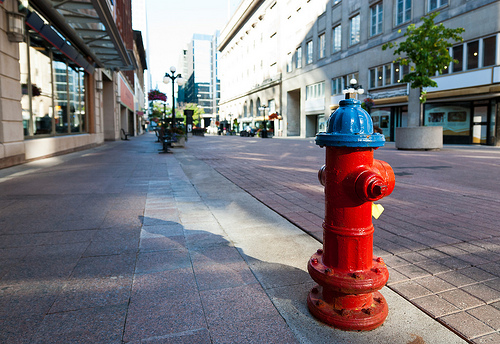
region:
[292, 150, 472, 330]
the hydrant is red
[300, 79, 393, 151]
the top is blue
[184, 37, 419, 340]
the hydrant is at the sidewalk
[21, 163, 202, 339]
the floor is bricked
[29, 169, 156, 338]
the ground is red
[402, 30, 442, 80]
the leaves are green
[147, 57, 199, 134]
the lamp post is off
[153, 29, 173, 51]
the sky is white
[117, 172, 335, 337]
the shadow on the ground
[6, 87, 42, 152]
the wall is beige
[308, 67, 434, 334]
Fire hydrant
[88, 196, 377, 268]
Brick pavers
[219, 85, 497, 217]
Stores along the walkway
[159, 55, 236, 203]
Street lights along the walkway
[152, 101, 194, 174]
Benches along the walkway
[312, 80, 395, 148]
Blue top on the fire hydrant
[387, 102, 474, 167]
A concrete planter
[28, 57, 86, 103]
Windows on the side of the building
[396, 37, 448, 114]
A tree along the walkway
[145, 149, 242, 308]
Brick pavers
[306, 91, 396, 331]
metal clean fire hydrant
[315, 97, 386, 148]
blue top on fire hydrant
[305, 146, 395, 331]
bottom of fire hydrant is red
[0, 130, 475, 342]
fire hydrant on sidewalk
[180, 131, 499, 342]
brick street next to fire hydrant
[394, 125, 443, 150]
cement planter behind fire hydrant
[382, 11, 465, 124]
green tree in planter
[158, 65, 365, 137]
four street lights near street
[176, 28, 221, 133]
glass building behind street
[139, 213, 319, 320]
long shadow of fire hydrant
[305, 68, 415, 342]
Fire hydrant in the middle of the city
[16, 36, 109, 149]
Windows of a downtown building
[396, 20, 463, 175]
Tree growing from a pot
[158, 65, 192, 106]
Light fixture in downtown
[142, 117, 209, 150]
Table outside of a building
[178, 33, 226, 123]
Skyscraper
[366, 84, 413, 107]
Sign on a building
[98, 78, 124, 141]
Doorway to a building downtown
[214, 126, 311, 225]
Street in the middle of downtown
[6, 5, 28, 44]
light fixture on the side of a building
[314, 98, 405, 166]
blue top on hydrant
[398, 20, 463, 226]
tree across the walkway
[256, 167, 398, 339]
hydrant on the curb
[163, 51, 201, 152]
streetlight in background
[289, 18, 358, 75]
a bunch of windows on the building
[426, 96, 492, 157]
advertisement on the building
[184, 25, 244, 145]
tall building in the background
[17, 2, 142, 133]
awning on the building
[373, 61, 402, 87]
lights are on inside the building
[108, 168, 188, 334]
this is the sidewalk